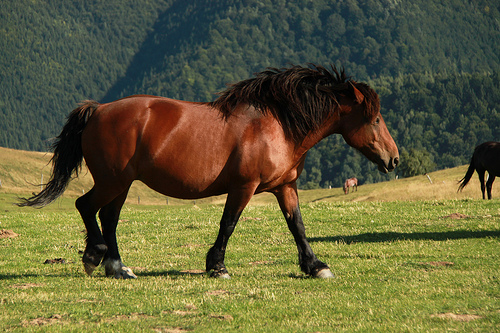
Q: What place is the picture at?
A: It is at the field.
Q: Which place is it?
A: It is a field.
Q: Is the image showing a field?
A: Yes, it is showing a field.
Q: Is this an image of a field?
A: Yes, it is showing a field.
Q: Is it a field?
A: Yes, it is a field.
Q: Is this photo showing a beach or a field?
A: It is showing a field.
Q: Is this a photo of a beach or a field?
A: It is showing a field.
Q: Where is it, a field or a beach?
A: It is a field.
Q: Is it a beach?
A: No, it is a field.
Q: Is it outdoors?
A: Yes, it is outdoors.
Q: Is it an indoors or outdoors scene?
A: It is outdoors.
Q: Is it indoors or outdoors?
A: It is outdoors.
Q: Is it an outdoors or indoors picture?
A: It is outdoors.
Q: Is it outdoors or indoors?
A: It is outdoors.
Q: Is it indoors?
A: No, it is outdoors.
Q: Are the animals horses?
A: Yes, all the animals are horses.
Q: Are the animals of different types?
A: No, all the animals are horses.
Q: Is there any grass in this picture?
A: Yes, there is grass.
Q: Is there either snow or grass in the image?
A: Yes, there is grass.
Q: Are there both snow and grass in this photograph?
A: No, there is grass but no snow.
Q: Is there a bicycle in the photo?
A: No, there are no bicycles.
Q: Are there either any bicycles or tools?
A: No, there are no bicycles or tools.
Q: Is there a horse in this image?
A: Yes, there is a horse.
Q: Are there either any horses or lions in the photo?
A: Yes, there is a horse.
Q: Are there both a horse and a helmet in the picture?
A: No, there is a horse but no helmets.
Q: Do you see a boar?
A: No, there are no boars.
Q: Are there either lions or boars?
A: No, there are no boars or lions.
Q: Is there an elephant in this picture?
A: No, there are no elephants.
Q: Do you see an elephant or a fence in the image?
A: No, there are no elephants or fences.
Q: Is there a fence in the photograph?
A: No, there are no fences.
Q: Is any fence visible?
A: No, there are no fences.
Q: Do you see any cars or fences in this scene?
A: No, there are no fences or cars.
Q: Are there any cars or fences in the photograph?
A: No, there are no fences or cars.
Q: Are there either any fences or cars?
A: No, there are no fences or cars.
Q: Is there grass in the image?
A: Yes, there is grass.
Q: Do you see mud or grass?
A: Yes, there is grass.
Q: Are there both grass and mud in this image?
A: No, there is grass but no mud.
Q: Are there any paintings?
A: No, there are no paintings.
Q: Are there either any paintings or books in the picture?
A: No, there are no paintings or books.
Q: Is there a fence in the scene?
A: No, there are no fences.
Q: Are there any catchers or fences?
A: No, there are no fences or catchers.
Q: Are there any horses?
A: Yes, there is a horse.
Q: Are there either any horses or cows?
A: Yes, there is a horse.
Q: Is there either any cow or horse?
A: Yes, there is a horse.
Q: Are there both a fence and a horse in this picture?
A: No, there is a horse but no fences.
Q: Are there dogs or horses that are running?
A: Yes, the horse is running.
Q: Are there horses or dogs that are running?
A: Yes, the horse is running.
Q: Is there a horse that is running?
A: Yes, there is a horse that is running.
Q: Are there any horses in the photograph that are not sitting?
A: Yes, there is a horse that is running.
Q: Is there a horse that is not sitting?
A: Yes, there is a horse that is running.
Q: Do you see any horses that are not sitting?
A: Yes, there is a horse that is running .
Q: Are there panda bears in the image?
A: No, there are no panda bears.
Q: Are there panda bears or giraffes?
A: No, there are no panda bears or giraffes.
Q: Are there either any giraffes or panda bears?
A: No, there are no panda bears or giraffes.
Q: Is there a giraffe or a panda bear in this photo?
A: No, there are no panda bears or giraffes.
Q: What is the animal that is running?
A: The animal is a horse.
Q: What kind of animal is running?
A: The animal is a horse.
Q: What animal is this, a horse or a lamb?
A: This is a horse.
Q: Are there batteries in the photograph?
A: No, there are no batteries.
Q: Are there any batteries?
A: No, there are no batteries.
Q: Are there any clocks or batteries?
A: No, there are no batteries or clocks.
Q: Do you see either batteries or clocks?
A: No, there are no batteries or clocks.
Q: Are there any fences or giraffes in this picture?
A: No, there are no fences or giraffes.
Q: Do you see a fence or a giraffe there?
A: No, there are no fences or giraffes.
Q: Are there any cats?
A: No, there are no cats.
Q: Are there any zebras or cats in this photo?
A: No, there are no cats or zebras.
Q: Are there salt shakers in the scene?
A: No, there are no salt shakers.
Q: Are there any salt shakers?
A: No, there are no salt shakers.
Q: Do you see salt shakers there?
A: No, there are no salt shakers.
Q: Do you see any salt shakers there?
A: No, there are no salt shakers.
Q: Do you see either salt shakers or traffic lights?
A: No, there are no salt shakers or traffic lights.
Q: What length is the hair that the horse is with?
A: The hair is long.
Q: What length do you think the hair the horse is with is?
A: The hair is long.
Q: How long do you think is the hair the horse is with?
A: The hair is long.